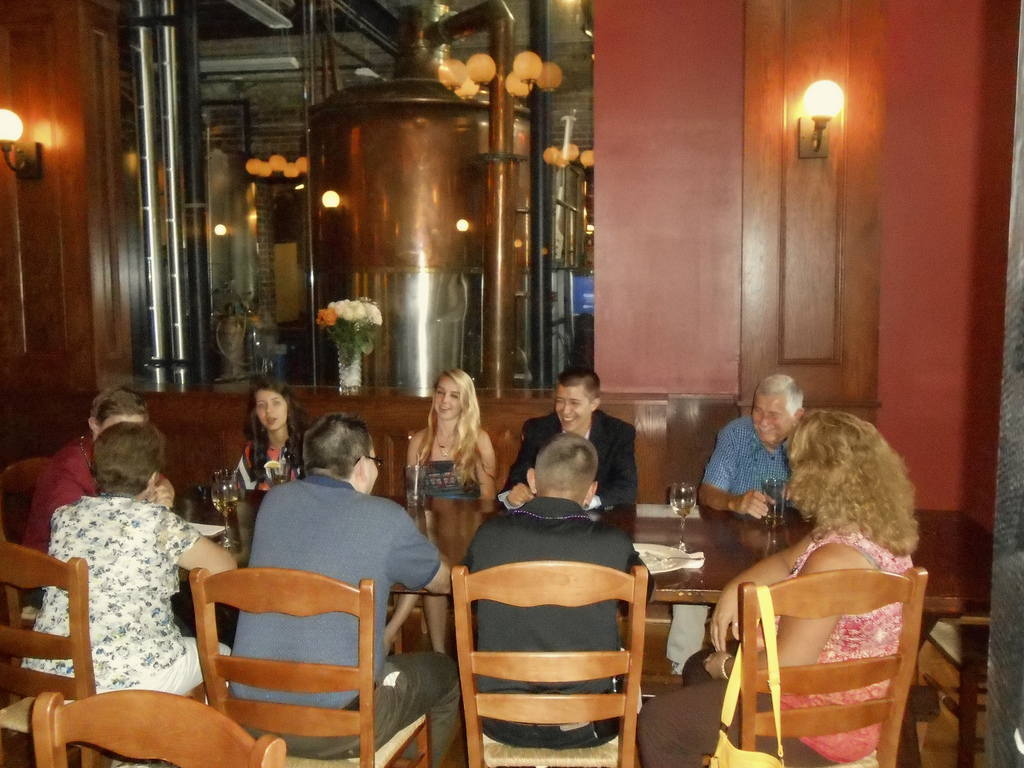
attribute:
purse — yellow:
[709, 578, 786, 766]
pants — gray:
[238, 639, 457, 764]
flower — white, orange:
[358, 302, 384, 331]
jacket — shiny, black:
[453, 495, 651, 704]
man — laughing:
[693, 370, 810, 522]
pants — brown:
[633, 679, 817, 765]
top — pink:
[770, 525, 927, 757]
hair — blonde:
[408, 366, 479, 499]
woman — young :
[371, 359, 504, 657]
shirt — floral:
[26, 495, 195, 686]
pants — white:
[131, 635, 227, 706]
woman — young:
[222, 381, 325, 506]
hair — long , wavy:
[244, 381, 306, 476]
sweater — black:
[456, 499, 653, 702]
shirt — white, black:
[38, 490, 201, 697]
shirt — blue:
[229, 467, 445, 718]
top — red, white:
[772, 524, 913, 758]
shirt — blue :
[708, 414, 795, 504]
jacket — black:
[509, 407, 636, 506]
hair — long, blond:
[413, 366, 490, 497]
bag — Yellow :
[713, 577, 786, 767]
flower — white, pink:
[315, 306, 341, 330]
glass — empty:
[669, 483, 701, 548]